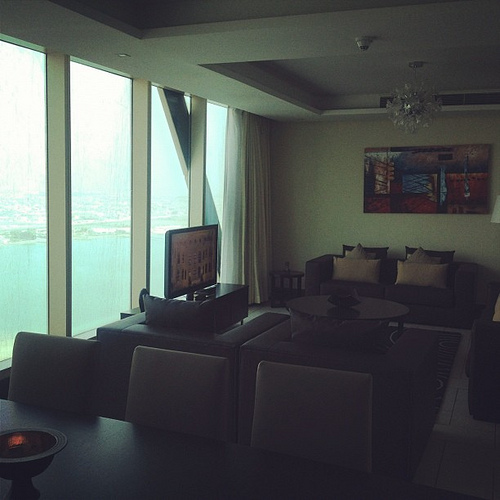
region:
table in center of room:
[284, 280, 401, 336]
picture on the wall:
[361, 131, 494, 221]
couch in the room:
[297, 230, 477, 323]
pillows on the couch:
[336, 233, 446, 285]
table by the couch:
[271, 259, 303, 297]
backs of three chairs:
[3, 320, 383, 452]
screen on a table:
[156, 222, 229, 295]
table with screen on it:
[197, 284, 256, 326]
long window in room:
[72, 68, 131, 317]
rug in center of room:
[440, 330, 457, 360]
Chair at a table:
[13, 318, 100, 430]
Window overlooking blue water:
[71, 117, 136, 320]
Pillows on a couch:
[322, 245, 452, 290]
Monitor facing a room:
[146, 230, 238, 290]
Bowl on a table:
[9, 423, 68, 472]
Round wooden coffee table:
[287, 268, 409, 330]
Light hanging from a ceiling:
[382, 81, 454, 143]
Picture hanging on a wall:
[354, 136, 490, 223]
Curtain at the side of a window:
[240, 123, 277, 307]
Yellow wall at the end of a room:
[286, 141, 334, 247]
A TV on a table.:
[153, 226, 223, 298]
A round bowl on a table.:
[0, 413, 67, 499]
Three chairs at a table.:
[11, 325, 394, 465]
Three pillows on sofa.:
[336, 243, 389, 286]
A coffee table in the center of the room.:
[277, 289, 419, 347]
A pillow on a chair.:
[131, 293, 217, 328]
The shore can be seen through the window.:
[7, 223, 37, 252]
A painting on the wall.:
[356, 143, 497, 220]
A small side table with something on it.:
[270, 256, 305, 298]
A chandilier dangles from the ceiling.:
[380, 75, 453, 138]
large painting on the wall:
[363, 142, 490, 213]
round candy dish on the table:
[1, 425, 67, 497]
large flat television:
[165, 223, 217, 297]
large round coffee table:
[286, 295, 407, 355]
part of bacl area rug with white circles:
[389, 324, 461, 426]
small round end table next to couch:
[271, 267, 303, 307]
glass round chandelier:
[383, 74, 443, 134]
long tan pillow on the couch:
[332, 257, 380, 284]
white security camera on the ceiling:
[356, 35, 372, 52]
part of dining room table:
[1, 398, 469, 497]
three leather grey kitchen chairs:
[9, 319, 391, 454]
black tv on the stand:
[154, 212, 230, 297]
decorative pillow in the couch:
[312, 235, 475, 287]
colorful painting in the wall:
[357, 140, 495, 215]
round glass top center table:
[288, 292, 416, 349]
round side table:
[266, 244, 306, 309]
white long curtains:
[220, 98, 275, 300]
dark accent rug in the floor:
[393, 316, 462, 410]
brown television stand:
[198, 278, 251, 328]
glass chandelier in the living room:
[371, 63, 458, 145]